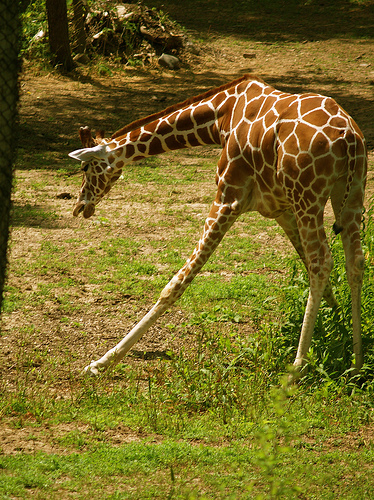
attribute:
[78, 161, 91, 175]
eyes — dark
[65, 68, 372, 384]
giraffe — thin, brown, curious, bending, tall, long, grazing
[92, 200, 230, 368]
front leg — long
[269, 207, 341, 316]
front leg — long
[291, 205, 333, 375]
back leg — long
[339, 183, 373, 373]
back leg — long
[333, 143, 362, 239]
giraffe tail — long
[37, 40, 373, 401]
giraffe — tall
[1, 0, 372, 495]
grass — growing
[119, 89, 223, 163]
neck — large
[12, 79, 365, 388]
giraffe — brown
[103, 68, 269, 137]
hair — short, brown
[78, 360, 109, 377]
giraffe hoof — cloven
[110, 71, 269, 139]
mane — short